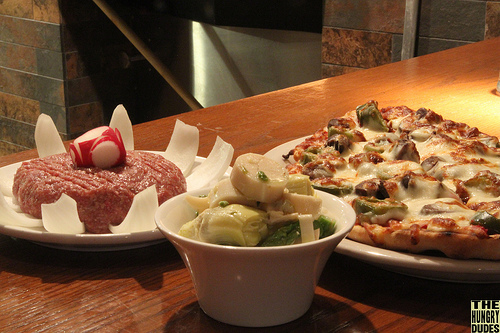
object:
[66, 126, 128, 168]
radish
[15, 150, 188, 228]
beef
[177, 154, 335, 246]
salad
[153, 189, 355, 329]
bowl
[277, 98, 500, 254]
pizza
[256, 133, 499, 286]
plate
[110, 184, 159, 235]
onion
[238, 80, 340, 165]
table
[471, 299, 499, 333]
watermark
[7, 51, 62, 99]
wall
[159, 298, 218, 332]
shadow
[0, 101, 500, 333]
food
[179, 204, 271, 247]
dumplings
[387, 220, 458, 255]
crust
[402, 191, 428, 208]
cheese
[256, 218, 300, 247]
vegetables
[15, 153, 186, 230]
dessert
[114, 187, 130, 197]
peppermint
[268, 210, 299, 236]
artichoke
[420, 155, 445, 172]
mushroom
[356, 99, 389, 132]
topping